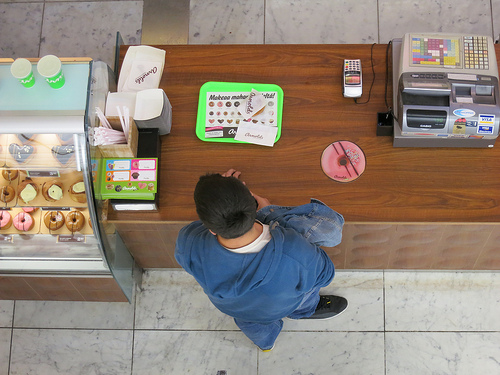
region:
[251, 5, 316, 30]
this is the floor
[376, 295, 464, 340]
the floor is made of tiles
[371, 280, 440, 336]
the tiles are big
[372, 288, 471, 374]
the tiles are white in color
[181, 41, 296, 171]
this is the counter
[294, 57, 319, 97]
the counter is wooden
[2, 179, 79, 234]
these are some doughnuts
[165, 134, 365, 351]
this is a person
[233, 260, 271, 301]
the hood is blue in color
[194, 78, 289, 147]
this is a tray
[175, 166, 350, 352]
man standing at checkout counter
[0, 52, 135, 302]
glass display case next to counter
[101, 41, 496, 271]
wooden checkout counter on tiled floor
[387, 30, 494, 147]
gray cash register on counter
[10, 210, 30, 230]
pink frosted donut in display case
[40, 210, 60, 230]
brown frosted donut next to pink donut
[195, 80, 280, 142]
bright green serving tray on counter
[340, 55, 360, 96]
black and silver credit card reader next to register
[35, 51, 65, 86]
large green paper cup on display case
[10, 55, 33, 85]
small green paper cup next to large paper cup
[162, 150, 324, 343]
man in blue at counter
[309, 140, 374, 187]
red cd on counter top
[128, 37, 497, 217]
wooden counter in front of man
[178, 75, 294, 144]
green mat on counter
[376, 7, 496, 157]
cash register on counter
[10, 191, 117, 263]
doughnuts on counter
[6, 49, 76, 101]
green cups on case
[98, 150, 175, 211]
green box on counter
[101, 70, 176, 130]
stacks of trays on left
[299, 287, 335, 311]
black shoes on man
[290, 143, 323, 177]
part of a table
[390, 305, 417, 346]
part of a floor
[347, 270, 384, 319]
part of a floor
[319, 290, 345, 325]
par tof a shoe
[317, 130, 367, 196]
There is a large donut that is visible here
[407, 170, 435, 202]
There is a brown counter here that is lovely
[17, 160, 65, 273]
There is a case of donuts to the left of the counter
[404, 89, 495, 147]
There is a cash register that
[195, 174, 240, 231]
This man has a head full of black hair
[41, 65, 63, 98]
There is a cup that is visible here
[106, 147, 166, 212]
There are promotional flyers here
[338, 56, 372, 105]
There is a keypad that is visible here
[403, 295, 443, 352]
There is white tile in this restaurant here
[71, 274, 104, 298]
There is brown trim that is on the donut case